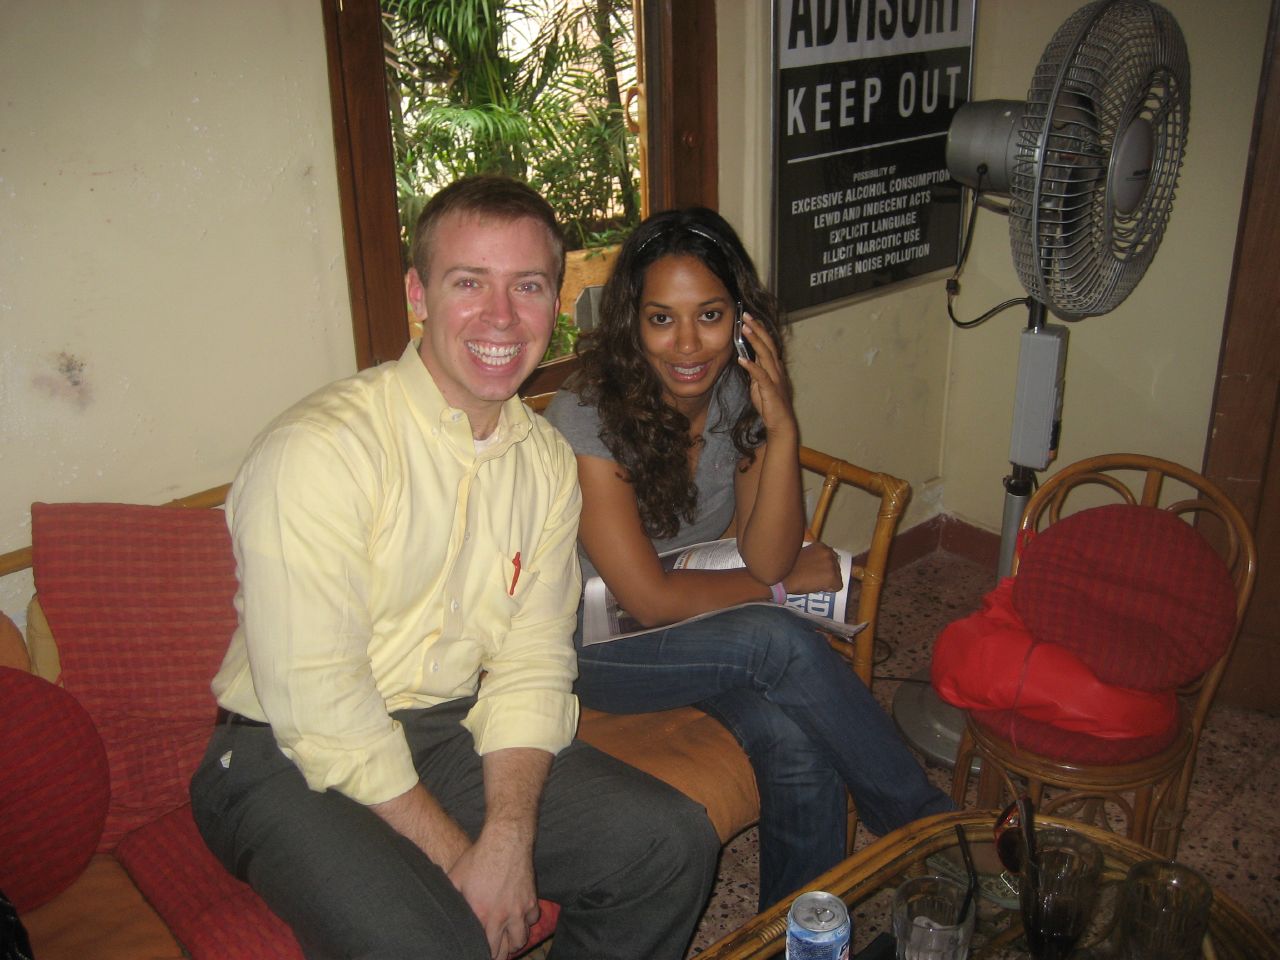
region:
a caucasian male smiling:
[397, 159, 561, 413]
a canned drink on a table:
[778, 876, 869, 956]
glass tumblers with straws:
[864, 761, 1112, 958]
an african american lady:
[595, 192, 807, 537]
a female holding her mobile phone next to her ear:
[560, 196, 810, 492]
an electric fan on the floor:
[902, 4, 1207, 788]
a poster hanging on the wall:
[772, 2, 1017, 336]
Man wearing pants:
[184, 678, 752, 957]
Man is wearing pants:
[177, 683, 758, 957]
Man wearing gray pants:
[182, 640, 741, 958]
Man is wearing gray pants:
[188, 676, 747, 957]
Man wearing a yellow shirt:
[208, 329, 612, 777]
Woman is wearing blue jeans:
[528, 566, 999, 917]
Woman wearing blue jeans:
[561, 572, 968, 913]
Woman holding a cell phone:
[718, 272, 782, 378]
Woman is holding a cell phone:
[713, 285, 778, 370]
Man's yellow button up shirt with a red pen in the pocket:
[208, 335, 588, 814]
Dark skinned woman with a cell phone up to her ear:
[541, 200, 963, 911]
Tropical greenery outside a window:
[367, 0, 646, 369]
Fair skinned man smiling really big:
[184, 168, 727, 957]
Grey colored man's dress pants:
[182, 695, 725, 954]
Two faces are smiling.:
[409, 182, 747, 399]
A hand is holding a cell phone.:
[727, 292, 785, 414]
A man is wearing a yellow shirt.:
[202, 341, 586, 796]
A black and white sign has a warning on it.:
[778, 0, 970, 292]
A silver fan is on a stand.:
[945, 5, 1182, 566]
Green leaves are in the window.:
[384, 1, 649, 359]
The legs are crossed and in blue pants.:
[577, 601, 920, 877]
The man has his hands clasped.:
[360, 753, 544, 941]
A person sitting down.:
[192, 177, 725, 957]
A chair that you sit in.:
[926, 449, 1256, 891]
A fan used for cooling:
[895, 0, 1198, 777]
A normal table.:
[681, 804, 1278, 957]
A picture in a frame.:
[767, 5, 979, 323]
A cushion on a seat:
[1008, 501, 1238, 705]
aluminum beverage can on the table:
[783, 883, 850, 957]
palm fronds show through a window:
[395, 0, 643, 235]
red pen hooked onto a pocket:
[502, 541, 529, 594]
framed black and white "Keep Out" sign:
[759, 7, 983, 325]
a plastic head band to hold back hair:
[626, 221, 737, 257]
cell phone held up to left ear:
[725, 300, 759, 371]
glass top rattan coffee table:
[699, 790, 1278, 936]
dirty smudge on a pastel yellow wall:
[19, 338, 117, 440]